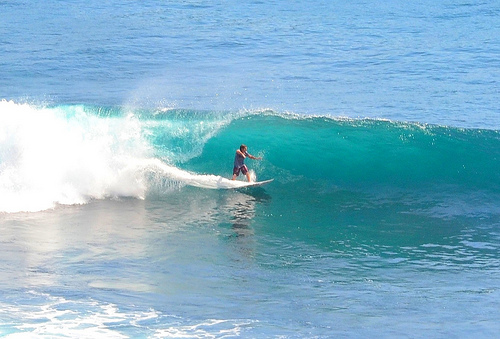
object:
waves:
[308, 115, 444, 165]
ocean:
[23, 36, 445, 323]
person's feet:
[248, 180, 253, 184]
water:
[22, 79, 132, 212]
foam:
[23, 274, 151, 331]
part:
[328, 103, 374, 143]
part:
[149, 112, 246, 175]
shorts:
[234, 164, 249, 175]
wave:
[4, 96, 498, 216]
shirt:
[234, 151, 247, 168]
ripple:
[214, 38, 248, 48]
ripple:
[183, 42, 222, 51]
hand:
[258, 155, 265, 159]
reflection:
[219, 187, 253, 262]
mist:
[122, 57, 171, 114]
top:
[261, 109, 497, 139]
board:
[183, 176, 274, 190]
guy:
[232, 144, 261, 183]